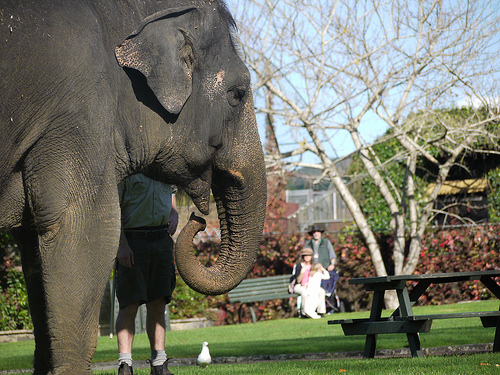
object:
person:
[290, 246, 328, 320]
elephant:
[1, 0, 271, 374]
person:
[303, 225, 337, 314]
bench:
[224, 271, 340, 322]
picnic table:
[326, 264, 499, 361]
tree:
[206, 0, 499, 313]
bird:
[195, 339, 212, 370]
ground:
[1, 297, 500, 375]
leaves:
[490, 231, 497, 238]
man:
[111, 169, 181, 375]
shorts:
[111, 224, 179, 310]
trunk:
[173, 89, 268, 298]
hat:
[299, 247, 314, 256]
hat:
[307, 223, 325, 237]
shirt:
[115, 170, 180, 232]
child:
[305, 262, 331, 319]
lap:
[293, 283, 326, 297]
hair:
[308, 262, 323, 278]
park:
[0, 105, 498, 375]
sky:
[216, 0, 500, 176]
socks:
[149, 349, 170, 368]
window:
[430, 193, 490, 227]